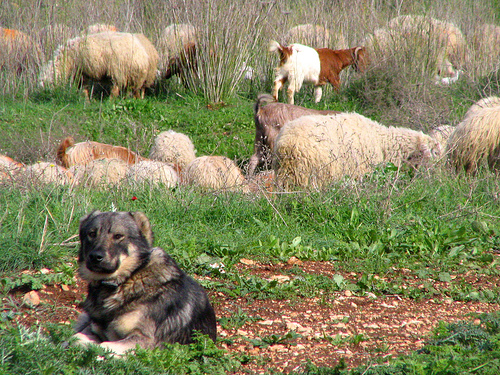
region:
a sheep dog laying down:
[37, 153, 254, 371]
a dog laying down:
[22, 167, 310, 373]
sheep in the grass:
[79, 6, 499, 298]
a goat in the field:
[253, 20, 415, 148]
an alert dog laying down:
[36, 153, 263, 373]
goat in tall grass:
[39, 9, 497, 318]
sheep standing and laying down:
[22, 7, 497, 352]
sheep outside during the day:
[44, 17, 497, 337]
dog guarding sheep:
[22, 135, 240, 372]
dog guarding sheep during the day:
[29, 162, 304, 373]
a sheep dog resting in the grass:
[64, 195, 217, 365]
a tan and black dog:
[58, 206, 220, 366]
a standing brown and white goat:
[265, 30, 373, 105]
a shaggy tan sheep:
[260, 105, 430, 185]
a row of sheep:
[7, 110, 497, 196]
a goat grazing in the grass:
[264, 37, 369, 103]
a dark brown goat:
[243, 88, 333, 162]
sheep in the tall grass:
[4, 0, 496, 100]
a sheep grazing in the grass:
[154, 21, 204, 91]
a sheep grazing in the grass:
[146, 126, 195, 170]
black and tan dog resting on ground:
[54, 210, 219, 350]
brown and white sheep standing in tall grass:
[261, 32, 373, 106]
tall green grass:
[200, 183, 384, 245]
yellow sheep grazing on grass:
[32, 33, 149, 105]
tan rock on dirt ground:
[17, 289, 49, 306]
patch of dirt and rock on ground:
[268, 305, 403, 354]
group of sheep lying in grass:
[3, 131, 243, 201]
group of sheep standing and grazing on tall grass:
[0, 18, 202, 106]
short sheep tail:
[259, 33, 287, 58]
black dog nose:
[86, 249, 107, 262]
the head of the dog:
[76, 210, 149, 277]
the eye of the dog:
[110, 227, 127, 241]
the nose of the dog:
[86, 249, 106, 264]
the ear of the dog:
[129, 207, 153, 244]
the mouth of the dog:
[81, 256, 121, 277]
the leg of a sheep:
[100, 77, 127, 103]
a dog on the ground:
[53, 197, 223, 370]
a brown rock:
[21, 287, 48, 309]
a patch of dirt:
[0, 250, 499, 374]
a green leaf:
[288, 232, 308, 246]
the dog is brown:
[65, 184, 214, 371]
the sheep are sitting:
[37, 90, 442, 246]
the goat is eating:
[259, 26, 428, 133]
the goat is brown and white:
[259, 25, 406, 115]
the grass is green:
[135, 175, 375, 282]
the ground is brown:
[237, 306, 417, 361]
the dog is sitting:
[64, 200, 233, 350]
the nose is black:
[87, 237, 112, 264]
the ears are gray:
[68, 205, 213, 257]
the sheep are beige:
[247, 103, 423, 199]